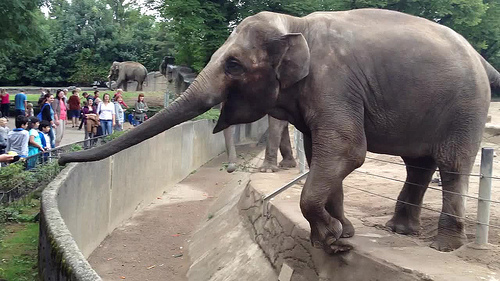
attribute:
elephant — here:
[60, 9, 500, 254]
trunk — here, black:
[57, 79, 216, 166]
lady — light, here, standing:
[53, 89, 71, 149]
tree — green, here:
[0, 1, 499, 99]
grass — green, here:
[1, 92, 224, 281]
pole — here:
[475, 147, 495, 250]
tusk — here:
[107, 73, 112, 80]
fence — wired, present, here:
[223, 123, 500, 250]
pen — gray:
[40, 104, 499, 280]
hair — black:
[14, 115, 29, 129]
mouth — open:
[213, 98, 268, 134]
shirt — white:
[96, 99, 118, 121]